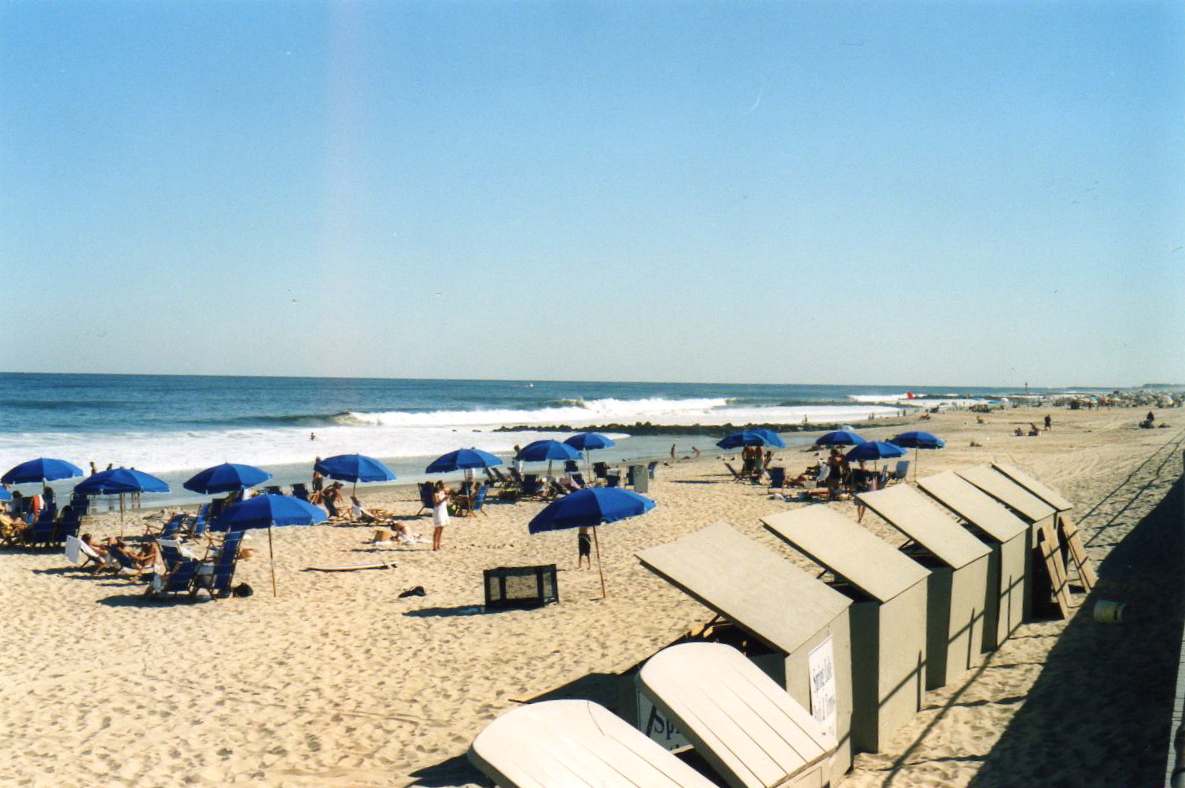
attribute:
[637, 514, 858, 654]
lid — open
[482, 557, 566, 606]
crib — black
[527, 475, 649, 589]
umbrella — blue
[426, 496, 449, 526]
dress — white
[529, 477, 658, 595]
umbrella — blue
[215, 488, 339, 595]
umbrella — blue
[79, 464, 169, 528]
umbrella — blue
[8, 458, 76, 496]
umbrella — blue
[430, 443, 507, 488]
umbrella — blue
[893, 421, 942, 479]
umbrella — blue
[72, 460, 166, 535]
umbrella — open, large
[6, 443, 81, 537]
umbrella — large, open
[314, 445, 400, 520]
umbrella — blue, open, large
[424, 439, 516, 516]
umbrella — large, open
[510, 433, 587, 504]
umbrella — open, large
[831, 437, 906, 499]
umbrella — large, open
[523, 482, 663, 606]
umbrella — blue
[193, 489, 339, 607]
umbrella — blue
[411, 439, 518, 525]
umbrella — blue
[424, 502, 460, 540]
dress — white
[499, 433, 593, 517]
umbrella — blue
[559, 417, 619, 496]
umbrella — blue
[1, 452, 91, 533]
umbrella — blue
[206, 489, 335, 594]
umbrella — large, open